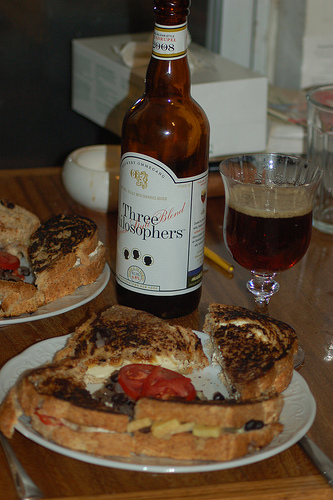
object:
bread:
[202, 301, 297, 401]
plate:
[0, 324, 317, 477]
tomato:
[118, 363, 196, 401]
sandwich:
[0, 365, 285, 470]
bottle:
[115, 0, 211, 320]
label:
[115, 152, 208, 297]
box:
[71, 31, 267, 160]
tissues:
[111, 40, 154, 67]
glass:
[217, 152, 321, 331]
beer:
[224, 182, 314, 276]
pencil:
[203, 245, 235, 275]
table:
[0, 171, 330, 499]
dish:
[62, 143, 127, 213]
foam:
[226, 184, 311, 220]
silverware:
[2, 426, 46, 500]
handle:
[299, 433, 333, 490]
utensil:
[291, 434, 333, 485]